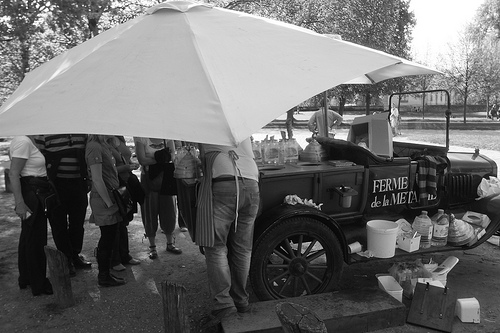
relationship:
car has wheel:
[175, 89, 500, 301] [252, 213, 353, 302]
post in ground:
[159, 278, 191, 330] [1, 127, 498, 331]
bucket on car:
[357, 212, 397, 269] [175, 89, 500, 301]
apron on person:
[196, 145, 217, 247] [195, 137, 261, 330]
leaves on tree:
[44, 16, 59, 30] [0, 0, 60, 62]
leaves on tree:
[24, 25, 39, 34] [0, 0, 60, 62]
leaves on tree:
[0, 24, 6, 34] [0, 0, 60, 62]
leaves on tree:
[43, 46, 50, 56] [0, 0, 60, 62]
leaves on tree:
[110, 8, 122, 20] [0, 0, 60, 62]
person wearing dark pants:
[192, 136, 263, 318] [45, 180, 95, 254]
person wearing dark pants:
[132, 136, 185, 261] [15, 187, 53, 295]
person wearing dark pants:
[85, 134, 128, 288] [45, 180, 95, 254]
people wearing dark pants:
[34, 134, 92, 277] [15, 187, 53, 295]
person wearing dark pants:
[2, 131, 53, 298] [45, 180, 95, 254]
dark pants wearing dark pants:
[45, 180, 95, 254] [15, 187, 53, 295]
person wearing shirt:
[195, 137, 261, 330] [206, 137, 287, 193]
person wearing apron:
[195, 137, 261, 330] [194, 148, 257, 248]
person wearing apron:
[8, 135, 57, 296] [194, 148, 257, 248]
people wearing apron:
[34, 134, 92, 277] [194, 148, 257, 248]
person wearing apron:
[85, 134, 128, 288] [194, 148, 257, 248]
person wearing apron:
[132, 136, 185, 261] [194, 148, 257, 248]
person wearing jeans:
[195, 137, 261, 330] [199, 181, 279, 316]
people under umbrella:
[11, 144, 255, 306] [0, 5, 397, 143]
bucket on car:
[366, 219, 400, 258] [250, 90, 499, 300]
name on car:
[370, 176, 437, 208] [201, 81, 498, 306]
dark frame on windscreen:
[368, 70, 470, 160] [351, 78, 483, 145]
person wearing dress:
[195, 137, 261, 330] [80, 133, 148, 291]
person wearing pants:
[85, 133, 128, 287] [95, 222, 120, 279]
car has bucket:
[250, 90, 499, 300] [362, 218, 402, 261]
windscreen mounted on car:
[390, 91, 448, 148] [285, 106, 457, 222]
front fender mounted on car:
[237, 202, 354, 262] [175, 89, 500, 301]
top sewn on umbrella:
[144, 0, 214, 15] [4, 6, 464, 155]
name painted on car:
[369, 174, 439, 206] [175, 89, 500, 301]